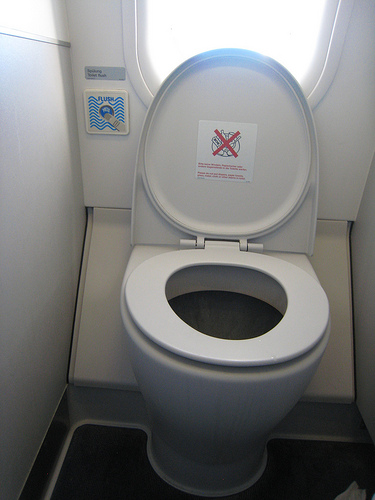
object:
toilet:
[0, 0, 373, 497]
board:
[54, 378, 370, 499]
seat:
[120, 232, 328, 372]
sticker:
[194, 120, 258, 185]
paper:
[335, 480, 368, 499]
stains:
[203, 395, 252, 465]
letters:
[211, 128, 241, 158]